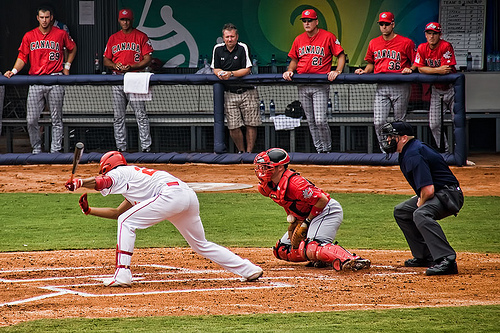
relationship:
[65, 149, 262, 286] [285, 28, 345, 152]
man wearing uniform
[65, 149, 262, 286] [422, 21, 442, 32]
man wearing cap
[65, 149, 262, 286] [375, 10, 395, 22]
man wearing cap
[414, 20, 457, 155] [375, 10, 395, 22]
man wearing cap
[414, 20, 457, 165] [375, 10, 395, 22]
man wearing cap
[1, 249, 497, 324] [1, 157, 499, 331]
sand on baseball field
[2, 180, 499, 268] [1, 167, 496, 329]
grass on field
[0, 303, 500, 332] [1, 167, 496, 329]
grass on field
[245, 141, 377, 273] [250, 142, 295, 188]
person wearing mask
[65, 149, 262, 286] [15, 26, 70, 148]
man wearing uniform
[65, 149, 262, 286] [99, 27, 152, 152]
man wearing uniform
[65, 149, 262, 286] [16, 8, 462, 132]
man wearing uniforms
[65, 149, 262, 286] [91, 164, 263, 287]
man wearing uniform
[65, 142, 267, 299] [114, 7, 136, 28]
man wearing cap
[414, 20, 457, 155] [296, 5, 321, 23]
man wearing cap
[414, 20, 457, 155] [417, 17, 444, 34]
man wearing cap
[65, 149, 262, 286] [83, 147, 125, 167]
man has helmet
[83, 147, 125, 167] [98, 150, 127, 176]
helmet on head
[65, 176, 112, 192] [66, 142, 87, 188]
arm has bat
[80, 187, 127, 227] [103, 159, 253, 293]
arm of person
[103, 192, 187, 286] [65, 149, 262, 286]
leg of man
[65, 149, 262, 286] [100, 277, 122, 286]
man with foot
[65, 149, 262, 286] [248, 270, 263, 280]
man with foot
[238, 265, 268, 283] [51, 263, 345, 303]
feet on dirt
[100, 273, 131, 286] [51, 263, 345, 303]
feet on dirt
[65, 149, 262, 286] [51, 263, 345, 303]
man on dirt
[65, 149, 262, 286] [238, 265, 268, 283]
man with feet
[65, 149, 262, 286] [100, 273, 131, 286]
man with feet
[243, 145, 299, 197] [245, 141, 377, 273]
head of person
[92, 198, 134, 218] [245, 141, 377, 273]
arm of person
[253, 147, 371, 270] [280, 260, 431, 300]
person on ground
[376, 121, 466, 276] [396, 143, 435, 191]
umpire wearing shirt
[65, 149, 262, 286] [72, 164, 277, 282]
man wearing uniform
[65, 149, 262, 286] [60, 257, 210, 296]
man on base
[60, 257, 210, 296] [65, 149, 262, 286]
base with man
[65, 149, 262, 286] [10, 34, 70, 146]
man with uniform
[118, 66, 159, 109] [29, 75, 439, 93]
towel hanging rail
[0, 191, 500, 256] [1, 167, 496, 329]
grass on field